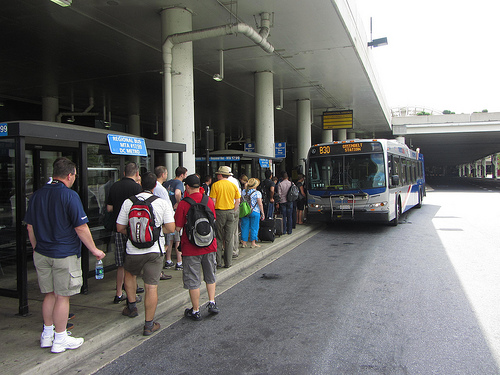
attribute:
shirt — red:
[25, 177, 95, 257]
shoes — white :
[37, 329, 85, 354]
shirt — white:
[121, 191, 215, 279]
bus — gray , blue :
[303, 131, 439, 235]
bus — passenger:
[267, 90, 454, 257]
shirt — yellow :
[209, 176, 240, 211]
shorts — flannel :
[115, 230, 128, 269]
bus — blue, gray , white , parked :
[301, 134, 426, 226]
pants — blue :
[241, 212, 261, 240]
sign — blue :
[107, 133, 149, 158]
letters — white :
[113, 136, 144, 155]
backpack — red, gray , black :
[129, 194, 161, 249]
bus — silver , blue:
[309, 135, 435, 227]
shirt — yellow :
[207, 177, 244, 211]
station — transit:
[1, 1, 497, 372]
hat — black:
[182, 168, 210, 191]